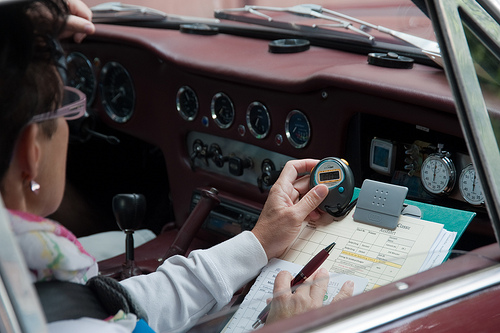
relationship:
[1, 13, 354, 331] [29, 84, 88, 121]
woman wearing glasses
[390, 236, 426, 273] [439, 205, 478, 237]
paper on board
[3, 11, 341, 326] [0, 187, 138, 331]
lady in seat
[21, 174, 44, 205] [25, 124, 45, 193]
earring in ear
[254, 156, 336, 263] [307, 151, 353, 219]
hand holding pedometer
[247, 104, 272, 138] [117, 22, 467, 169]
gauge in dashboard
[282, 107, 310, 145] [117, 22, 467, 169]
gauge in dashboard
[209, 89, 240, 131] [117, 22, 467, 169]
gauge in dashboard